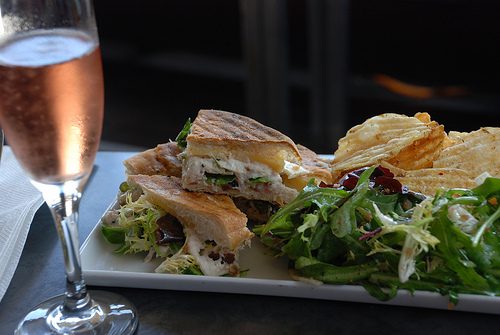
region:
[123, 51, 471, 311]
nice food on dish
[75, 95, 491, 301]
nice tasty food on dish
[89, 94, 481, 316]
tasty food on dish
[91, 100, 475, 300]
flavorful food on dish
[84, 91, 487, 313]
great food on dish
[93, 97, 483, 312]
well prepared food on dish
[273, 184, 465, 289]
green salad on plate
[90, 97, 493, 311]
delicious food on a dish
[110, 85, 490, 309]
nicely prepared food on dish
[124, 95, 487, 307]
nicely seasoned food on dish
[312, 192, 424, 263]
lettuce on a horizontal plate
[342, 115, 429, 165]
chips next to lettuce on a plate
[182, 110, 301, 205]
gourmet sandwich on a horiztontal plate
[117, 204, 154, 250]
green lettuce on a sandwich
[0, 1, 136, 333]
wine glass filled with sparkling champagne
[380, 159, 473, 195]
potato chip next to lettuce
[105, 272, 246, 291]
outer edge of plate with food on it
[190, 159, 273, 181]
turkey on a gourmet sandwich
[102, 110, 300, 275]
two gourmet sandwiches with lettuce on them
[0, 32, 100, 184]
sparkling champagne in a champagne glass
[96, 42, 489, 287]
A plate of food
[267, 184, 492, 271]
A green leafy salad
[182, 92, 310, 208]
A grilled chicken salad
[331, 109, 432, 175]
Potato chips with ridges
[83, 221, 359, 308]
A oblong white plate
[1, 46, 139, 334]
A long stemmed glass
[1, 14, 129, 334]
A clear glass with liquid in it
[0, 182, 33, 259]
A white napkin on table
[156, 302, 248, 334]
A grey table or counter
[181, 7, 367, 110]
A door or window with white trim in background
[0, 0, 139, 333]
this is a glass of wine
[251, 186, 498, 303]
this is a salad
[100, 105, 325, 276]
this is a sandwich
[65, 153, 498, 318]
this is a plate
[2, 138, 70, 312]
this is a paper napkin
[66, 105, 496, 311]
this is a plate of food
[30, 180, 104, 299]
this is the stem of the glass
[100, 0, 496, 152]
the room is dark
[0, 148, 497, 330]
this is a counter top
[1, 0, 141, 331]
a tall wine glass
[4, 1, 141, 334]
wine glass sitting on a black table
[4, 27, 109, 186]
white wine inside wine glass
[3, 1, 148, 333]
wine glass half full with white wine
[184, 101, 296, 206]
salad sandwich sitting on top of otheer salad sandwiches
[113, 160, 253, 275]
salad sandwich sitting on a white rectangular plate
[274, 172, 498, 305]
salad on top of a white plate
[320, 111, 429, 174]
potato chip on plate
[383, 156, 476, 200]
potato chip on plate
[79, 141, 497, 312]
white rectangular plate on black table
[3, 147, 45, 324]
napkin to the left of wine glass